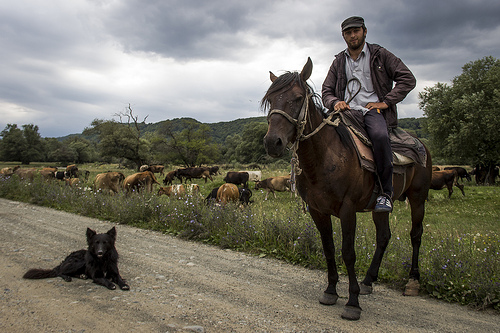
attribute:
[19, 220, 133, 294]
dog — black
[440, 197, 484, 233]
grass — green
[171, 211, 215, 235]
flowers — purple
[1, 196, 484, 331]
road — black, gray, dirt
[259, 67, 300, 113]
hair — black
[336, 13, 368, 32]
hat — gray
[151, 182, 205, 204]
cattle — white, brown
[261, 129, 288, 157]
nose — black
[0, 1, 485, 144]
sky — mostly cloudy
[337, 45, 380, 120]
shirt — gray